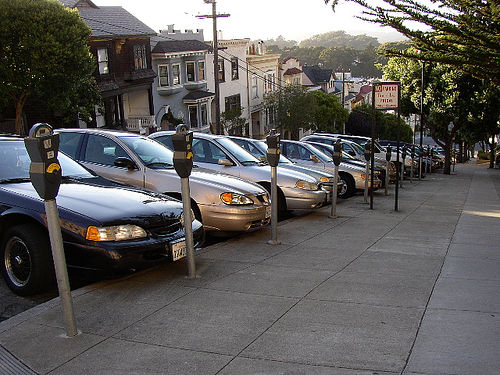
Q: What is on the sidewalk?
A: Parking meters.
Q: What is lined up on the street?
A: Cars.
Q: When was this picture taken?
A: Daytime.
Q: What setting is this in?
A: An urban setting.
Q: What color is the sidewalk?
A: Gray.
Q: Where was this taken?
A: On the sidewalk.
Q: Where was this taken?
A: Near the parking meters.